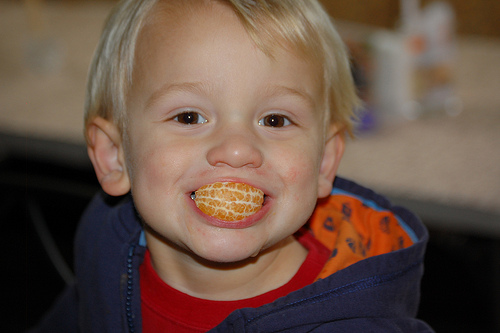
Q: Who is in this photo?
A: A boy.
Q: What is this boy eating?
A: An orange.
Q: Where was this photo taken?
A: In the kitchen.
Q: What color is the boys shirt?
A: Red.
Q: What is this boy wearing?
A: A jacket.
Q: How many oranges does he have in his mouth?
A: 1.